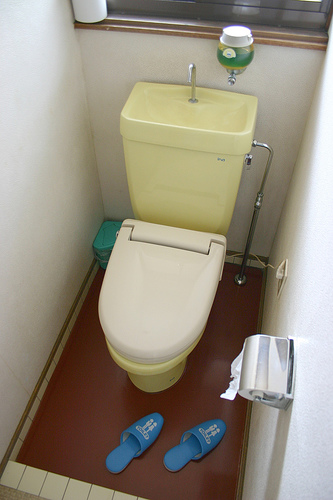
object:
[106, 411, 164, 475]
slippers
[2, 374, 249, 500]
floor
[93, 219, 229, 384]
seat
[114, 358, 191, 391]
basin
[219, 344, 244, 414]
paper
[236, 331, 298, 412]
holder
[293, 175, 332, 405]
wall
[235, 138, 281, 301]
pipe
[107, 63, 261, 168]
sink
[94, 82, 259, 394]
toilet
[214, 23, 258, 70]
soap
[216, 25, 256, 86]
dispenser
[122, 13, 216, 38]
windowsill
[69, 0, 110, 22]
paper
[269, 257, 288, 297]
outlet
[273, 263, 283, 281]
plug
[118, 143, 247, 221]
watertank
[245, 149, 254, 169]
handle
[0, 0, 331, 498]
bathroom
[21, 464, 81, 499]
tiles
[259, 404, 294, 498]
shadow